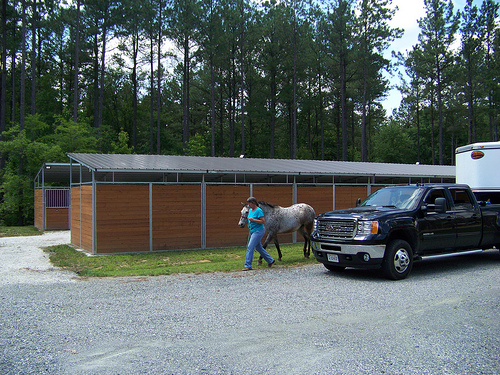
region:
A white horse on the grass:
[238, 200, 316, 258]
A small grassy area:
[41, 243, 319, 275]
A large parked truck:
[305, 181, 499, 282]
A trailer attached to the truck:
[455, 138, 499, 198]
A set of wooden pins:
[68, 151, 455, 254]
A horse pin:
[33, 158, 73, 237]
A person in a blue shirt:
[242, 196, 272, 268]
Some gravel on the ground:
[2, 230, 499, 374]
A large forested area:
[1, 2, 499, 224]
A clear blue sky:
[5, 0, 499, 120]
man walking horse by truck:
[230, 200, 332, 266]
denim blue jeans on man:
[231, 240, 285, 282]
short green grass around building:
[65, 240, 334, 308]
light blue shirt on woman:
[233, 204, 283, 232]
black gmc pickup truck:
[338, 180, 490, 277]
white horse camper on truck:
[440, 135, 498, 192]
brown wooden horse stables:
[69, 155, 487, 292]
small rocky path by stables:
[9, 222, 77, 292]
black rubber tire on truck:
[383, 240, 428, 284]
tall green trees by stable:
[55, 37, 497, 157]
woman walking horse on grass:
[182, 184, 389, 276]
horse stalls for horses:
[27, 134, 422, 281]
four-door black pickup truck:
[294, 157, 493, 314]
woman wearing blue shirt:
[222, 187, 294, 291]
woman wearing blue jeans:
[232, 195, 284, 298]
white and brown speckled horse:
[237, 187, 324, 269]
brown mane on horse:
[231, 200, 328, 256]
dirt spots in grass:
[83, 252, 243, 274]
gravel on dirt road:
[4, 247, 459, 372]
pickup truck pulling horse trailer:
[377, 117, 498, 294]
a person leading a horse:
[232, 200, 274, 268]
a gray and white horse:
[238, 202, 310, 256]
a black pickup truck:
[307, 181, 495, 283]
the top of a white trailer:
[434, 142, 499, 192]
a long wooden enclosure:
[67, 182, 370, 253]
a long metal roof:
[80, 153, 450, 179]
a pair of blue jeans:
[245, 226, 271, 266]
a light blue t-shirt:
[241, 205, 266, 236]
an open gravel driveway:
[12, 286, 485, 373]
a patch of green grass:
[67, 242, 294, 269]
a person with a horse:
[235, 195, 325, 278]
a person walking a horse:
[233, 195, 326, 271]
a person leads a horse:
[226, 179, 332, 269]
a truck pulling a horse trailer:
[310, 127, 499, 280]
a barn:
[26, 133, 476, 260]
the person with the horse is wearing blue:
[221, 189, 318, 269]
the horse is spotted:
[234, 193, 321, 268]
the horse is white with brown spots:
[231, 193, 321, 267]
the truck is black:
[310, 170, 498, 280]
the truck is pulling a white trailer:
[305, 131, 499, 283]